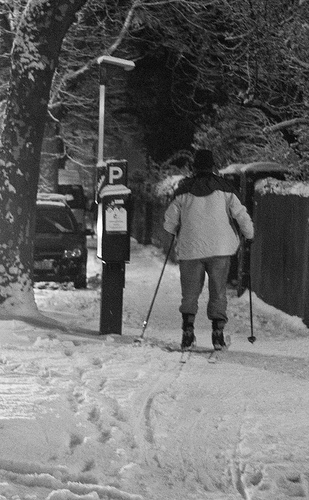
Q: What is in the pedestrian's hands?
A: Ski poles.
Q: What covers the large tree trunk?
A: Snow.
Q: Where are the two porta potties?
A: Right of the man.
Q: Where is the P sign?
A: On the meter left of the man.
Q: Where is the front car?
A: Parked behind tree.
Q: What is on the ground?
A: Snow.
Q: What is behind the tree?
A: Car.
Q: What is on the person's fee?
A: Skis.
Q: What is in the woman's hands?
A: Ski poles.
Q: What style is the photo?
A: Black and white.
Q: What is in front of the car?
A: Tree.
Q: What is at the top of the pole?
A: Light.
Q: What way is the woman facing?
A: Away from the camera.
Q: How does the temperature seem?
A: Cold.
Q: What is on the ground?
A: Snow.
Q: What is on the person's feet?
A: Skis.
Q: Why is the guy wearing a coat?
A: It is cold.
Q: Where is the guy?
A: On the sidewalk.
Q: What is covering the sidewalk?
A: Snow.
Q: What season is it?
A: Winter.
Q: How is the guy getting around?
A: Skiing.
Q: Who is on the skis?
A: A guy.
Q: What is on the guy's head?
A: A hat.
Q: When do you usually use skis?
A: When it snows.